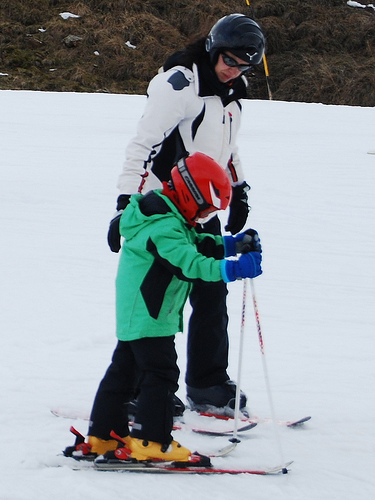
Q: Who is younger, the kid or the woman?
A: The kid is younger than the woman.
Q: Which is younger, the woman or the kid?
A: The kid is younger than the woman.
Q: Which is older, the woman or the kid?
A: The woman is older than the kid.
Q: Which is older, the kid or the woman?
A: The woman is older than the kid.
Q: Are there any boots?
A: Yes, there are boots.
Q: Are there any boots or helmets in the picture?
A: Yes, there are boots.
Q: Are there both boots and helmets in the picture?
A: Yes, there are both boots and a helmet.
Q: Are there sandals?
A: No, there are no sandals.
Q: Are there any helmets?
A: Yes, there is a helmet.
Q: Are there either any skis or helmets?
A: Yes, there is a helmet.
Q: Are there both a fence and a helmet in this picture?
A: No, there is a helmet but no fences.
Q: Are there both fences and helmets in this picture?
A: No, there is a helmet but no fences.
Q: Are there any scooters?
A: No, there are no scooters.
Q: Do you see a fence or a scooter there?
A: No, there are no scooters or fences.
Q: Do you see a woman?
A: Yes, there is a woman.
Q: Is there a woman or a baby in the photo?
A: Yes, there is a woman.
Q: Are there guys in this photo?
A: No, there are no guys.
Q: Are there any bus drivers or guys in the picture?
A: No, there are no guys or bus drivers.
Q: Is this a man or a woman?
A: This is a woman.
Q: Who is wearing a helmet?
A: The woman is wearing a helmet.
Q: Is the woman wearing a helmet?
A: Yes, the woman is wearing a helmet.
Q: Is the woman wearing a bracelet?
A: No, the woman is wearing a helmet.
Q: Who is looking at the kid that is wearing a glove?
A: The woman is looking at the child.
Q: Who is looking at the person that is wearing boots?
A: The woman is looking at the child.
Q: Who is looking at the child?
A: The woman is looking at the child.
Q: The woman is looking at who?
A: The woman is looking at the child.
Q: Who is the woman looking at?
A: The woman is looking at the child.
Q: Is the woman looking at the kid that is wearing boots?
A: Yes, the woman is looking at the child.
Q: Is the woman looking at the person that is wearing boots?
A: Yes, the woman is looking at the child.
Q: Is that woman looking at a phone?
A: No, the woman is looking at the child.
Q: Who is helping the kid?
A: The woman is helping the kid.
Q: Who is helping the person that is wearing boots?
A: The woman is helping the kid.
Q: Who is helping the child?
A: The woman is helping the kid.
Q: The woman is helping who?
A: The woman is helping the kid.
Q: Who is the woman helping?
A: The woman is helping the kid.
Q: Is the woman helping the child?
A: Yes, the woman is helping the child.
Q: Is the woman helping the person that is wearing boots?
A: Yes, the woman is helping the child.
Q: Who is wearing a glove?
A: The woman is wearing a glove.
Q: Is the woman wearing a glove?
A: Yes, the woman is wearing a glove.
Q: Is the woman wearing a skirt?
A: No, the woman is wearing a glove.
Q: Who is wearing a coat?
A: The woman is wearing a coat.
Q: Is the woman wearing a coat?
A: Yes, the woman is wearing a coat.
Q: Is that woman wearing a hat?
A: No, the woman is wearing a coat.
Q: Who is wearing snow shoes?
A: The woman is wearing snow shoes.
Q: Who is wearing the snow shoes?
A: The woman is wearing snow shoes.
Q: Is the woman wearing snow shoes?
A: Yes, the woman is wearing snow shoes.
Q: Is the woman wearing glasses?
A: No, the woman is wearing snow shoes.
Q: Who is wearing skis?
A: The woman is wearing skis.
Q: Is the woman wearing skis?
A: Yes, the woman is wearing skis.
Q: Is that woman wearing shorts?
A: No, the woman is wearing skis.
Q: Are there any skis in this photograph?
A: Yes, there are skis.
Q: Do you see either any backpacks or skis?
A: Yes, there are skis.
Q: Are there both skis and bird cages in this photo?
A: No, there are skis but no bird cages.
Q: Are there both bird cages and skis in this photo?
A: No, there are skis but no bird cages.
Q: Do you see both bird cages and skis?
A: No, there are skis but no bird cages.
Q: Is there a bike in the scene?
A: No, there are no bikes.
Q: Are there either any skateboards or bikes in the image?
A: No, there are no bikes or skateboards.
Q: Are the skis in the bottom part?
A: Yes, the skis are in the bottom of the image.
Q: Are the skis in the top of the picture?
A: No, the skis are in the bottom of the image.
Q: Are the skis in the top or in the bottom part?
A: The skis are in the bottom of the image.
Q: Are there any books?
A: No, there are no books.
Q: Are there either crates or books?
A: No, there are no books or crates.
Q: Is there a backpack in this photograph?
A: No, there are no backpacks.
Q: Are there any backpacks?
A: No, there are no backpacks.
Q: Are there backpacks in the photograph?
A: No, there are no backpacks.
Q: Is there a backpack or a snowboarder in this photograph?
A: No, there are no backpacks or snowboarders.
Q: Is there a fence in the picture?
A: No, there are no fences.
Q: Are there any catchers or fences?
A: No, there are no fences or catchers.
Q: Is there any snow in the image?
A: Yes, there is snow.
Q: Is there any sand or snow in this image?
A: Yes, there is snow.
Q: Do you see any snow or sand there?
A: Yes, there is snow.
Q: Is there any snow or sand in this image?
A: Yes, there is snow.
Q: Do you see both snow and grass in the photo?
A: Yes, there are both snow and grass.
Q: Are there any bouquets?
A: No, there are no bouquets.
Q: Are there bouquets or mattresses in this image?
A: No, there are no bouquets or mattresses.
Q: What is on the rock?
A: The snow is on the rock.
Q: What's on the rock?
A: The snow is on the rock.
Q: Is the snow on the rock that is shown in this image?
A: Yes, the snow is on the rock.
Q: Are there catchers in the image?
A: No, there are no catchers.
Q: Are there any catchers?
A: No, there are no catchers.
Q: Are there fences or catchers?
A: No, there are no catchers or fences.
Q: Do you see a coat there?
A: Yes, there is a coat.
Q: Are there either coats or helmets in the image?
A: Yes, there is a coat.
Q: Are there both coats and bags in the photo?
A: No, there is a coat but no bags.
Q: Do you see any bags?
A: No, there are no bags.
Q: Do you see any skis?
A: Yes, there are skis.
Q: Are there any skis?
A: Yes, there are skis.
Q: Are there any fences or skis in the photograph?
A: Yes, there are skis.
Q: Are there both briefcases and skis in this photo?
A: No, there are skis but no briefcases.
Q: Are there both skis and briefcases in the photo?
A: No, there are skis but no briefcases.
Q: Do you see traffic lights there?
A: No, there are no traffic lights.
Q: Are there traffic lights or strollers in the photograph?
A: No, there are no traffic lights or strollers.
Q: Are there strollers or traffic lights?
A: No, there are no traffic lights or strollers.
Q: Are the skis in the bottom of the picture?
A: Yes, the skis are in the bottom of the image.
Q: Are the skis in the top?
A: No, the skis are in the bottom of the image.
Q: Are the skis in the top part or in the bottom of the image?
A: The skis are in the bottom of the image.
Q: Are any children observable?
A: Yes, there is a child.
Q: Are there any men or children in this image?
A: Yes, there is a child.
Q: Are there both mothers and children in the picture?
A: No, there is a child but no mothers.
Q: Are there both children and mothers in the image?
A: No, there is a child but no mothers.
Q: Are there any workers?
A: No, there are no workers.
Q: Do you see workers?
A: No, there are no workers.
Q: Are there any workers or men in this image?
A: No, there are no workers or men.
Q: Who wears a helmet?
A: The kid wears a helmet.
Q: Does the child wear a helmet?
A: Yes, the child wears a helmet.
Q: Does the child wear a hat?
A: No, the child wears a helmet.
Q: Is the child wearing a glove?
A: Yes, the child is wearing a glove.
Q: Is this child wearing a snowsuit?
A: No, the child is wearing a glove.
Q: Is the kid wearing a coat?
A: Yes, the kid is wearing a coat.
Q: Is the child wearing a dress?
A: No, the child is wearing a coat.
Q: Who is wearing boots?
A: The child is wearing boots.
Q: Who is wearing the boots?
A: The child is wearing boots.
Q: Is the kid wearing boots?
A: Yes, the kid is wearing boots.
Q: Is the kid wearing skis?
A: Yes, the kid is wearing skis.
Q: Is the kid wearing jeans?
A: No, the kid is wearing skis.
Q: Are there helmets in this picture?
A: Yes, there is a helmet.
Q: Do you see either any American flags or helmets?
A: Yes, there is a helmet.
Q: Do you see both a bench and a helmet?
A: No, there is a helmet but no benches.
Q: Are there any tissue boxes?
A: No, there are no tissue boxes.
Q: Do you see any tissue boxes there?
A: No, there are no tissue boxes.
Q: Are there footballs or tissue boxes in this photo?
A: No, there are no tissue boxes or footballs.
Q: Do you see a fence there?
A: No, there are no fences.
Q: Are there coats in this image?
A: Yes, there is a coat.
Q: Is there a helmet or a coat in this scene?
A: Yes, there is a coat.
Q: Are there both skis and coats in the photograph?
A: Yes, there are both a coat and skis.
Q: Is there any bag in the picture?
A: No, there are no bags.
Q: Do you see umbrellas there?
A: No, there are no umbrellas.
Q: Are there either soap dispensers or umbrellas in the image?
A: No, there are no umbrellas or soap dispensers.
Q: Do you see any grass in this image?
A: Yes, there is grass.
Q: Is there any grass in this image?
A: Yes, there is grass.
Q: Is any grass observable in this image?
A: Yes, there is grass.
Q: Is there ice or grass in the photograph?
A: Yes, there is grass.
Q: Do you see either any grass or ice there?
A: Yes, there is grass.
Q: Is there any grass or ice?
A: Yes, there is grass.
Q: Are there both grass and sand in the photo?
A: No, there is grass but no sand.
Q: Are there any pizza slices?
A: No, there are no pizza slices.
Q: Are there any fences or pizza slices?
A: No, there are no pizza slices or fences.